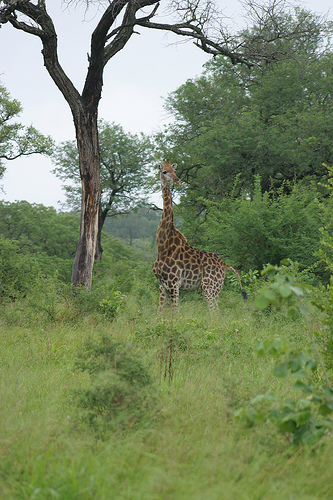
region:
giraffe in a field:
[149, 158, 247, 322]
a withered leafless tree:
[2, 0, 323, 309]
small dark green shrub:
[75, 329, 171, 450]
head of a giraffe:
[155, 159, 182, 185]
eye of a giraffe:
[161, 170, 166, 175]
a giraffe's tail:
[221, 261, 246, 299]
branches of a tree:
[0, 69, 56, 197]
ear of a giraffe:
[170, 161, 177, 169]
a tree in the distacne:
[165, 10, 332, 196]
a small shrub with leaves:
[245, 258, 331, 445]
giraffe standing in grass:
[146, 148, 248, 328]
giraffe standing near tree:
[48, 137, 260, 319]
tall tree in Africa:
[39, 0, 128, 315]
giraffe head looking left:
[149, 150, 187, 228]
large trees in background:
[189, 41, 325, 199]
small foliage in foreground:
[52, 335, 161, 447]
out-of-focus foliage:
[44, 326, 182, 453]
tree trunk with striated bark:
[47, 85, 111, 298]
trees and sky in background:
[103, 64, 232, 162]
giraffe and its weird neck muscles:
[134, 150, 193, 328]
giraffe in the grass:
[140, 147, 250, 335]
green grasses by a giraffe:
[21, 420, 306, 472]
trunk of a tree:
[67, 122, 125, 298]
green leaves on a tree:
[179, 60, 329, 175]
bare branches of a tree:
[152, 4, 220, 50]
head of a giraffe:
[154, 156, 193, 197]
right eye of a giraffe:
[160, 167, 165, 175]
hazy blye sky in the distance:
[9, 155, 42, 197]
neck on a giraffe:
[155, 182, 176, 234]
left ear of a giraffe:
[170, 155, 178, 171]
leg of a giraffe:
[164, 272, 182, 316]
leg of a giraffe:
[149, 280, 170, 317]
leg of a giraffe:
[199, 283, 226, 321]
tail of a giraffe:
[224, 261, 252, 302]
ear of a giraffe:
[155, 159, 162, 173]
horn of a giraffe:
[161, 156, 167, 165]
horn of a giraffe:
[165, 156, 172, 167]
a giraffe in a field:
[129, 150, 252, 362]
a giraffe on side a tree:
[5, 3, 247, 309]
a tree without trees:
[6, 0, 155, 306]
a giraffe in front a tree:
[146, 2, 331, 326]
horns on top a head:
[156, 152, 175, 169]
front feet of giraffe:
[147, 286, 185, 327]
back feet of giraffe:
[197, 286, 226, 324]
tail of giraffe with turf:
[223, 255, 253, 308]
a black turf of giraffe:
[236, 281, 252, 304]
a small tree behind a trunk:
[43, 85, 158, 304]